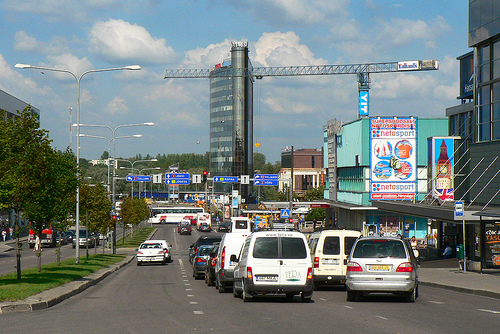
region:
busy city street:
[5, 219, 475, 332]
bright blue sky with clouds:
[0, 0, 499, 181]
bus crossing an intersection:
[138, 201, 205, 224]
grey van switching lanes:
[341, 231, 423, 304]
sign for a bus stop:
[451, 197, 470, 276]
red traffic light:
[198, 169, 208, 184]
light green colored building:
[319, 110, 452, 252]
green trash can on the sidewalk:
[453, 241, 465, 263]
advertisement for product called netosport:
[367, 111, 418, 207]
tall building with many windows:
[203, 40, 258, 207]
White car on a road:
[130, 231, 195, 274]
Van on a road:
[230, 224, 358, 303]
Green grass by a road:
[17, 254, 96, 300]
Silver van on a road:
[332, 221, 417, 299]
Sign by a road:
[361, 112, 421, 198]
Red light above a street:
[193, 164, 220, 183]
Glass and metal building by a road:
[198, 66, 270, 204]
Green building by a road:
[316, 117, 454, 224]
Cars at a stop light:
[184, 220, 309, 306]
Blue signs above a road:
[124, 145, 319, 200]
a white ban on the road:
[231, 229, 315, 299]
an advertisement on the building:
[368, 116, 417, 205]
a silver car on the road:
[346, 236, 420, 301]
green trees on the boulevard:
[2, 105, 74, 278]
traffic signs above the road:
[122, 168, 279, 189]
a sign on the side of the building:
[428, 133, 458, 204]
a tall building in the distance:
[206, 37, 254, 175]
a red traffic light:
[111, 212, 119, 254]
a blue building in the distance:
[321, 115, 452, 205]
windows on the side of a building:
[476, 43, 498, 140]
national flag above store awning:
[435, 189, 455, 205]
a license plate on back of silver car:
[365, 260, 391, 270]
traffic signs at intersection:
[165, 171, 190, 183]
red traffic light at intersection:
[200, 167, 207, 183]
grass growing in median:
[16, 282, 27, 292]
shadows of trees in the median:
[28, 270, 65, 280]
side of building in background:
[210, 116, 233, 147]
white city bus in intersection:
[150, 205, 202, 221]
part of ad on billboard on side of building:
[371, 135, 413, 185]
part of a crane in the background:
[346, 59, 382, 88]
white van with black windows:
[240, 230, 319, 298]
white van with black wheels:
[230, 227, 314, 294]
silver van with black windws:
[342, 233, 419, 303]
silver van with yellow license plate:
[345, 232, 421, 304]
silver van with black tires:
[345, 233, 419, 302]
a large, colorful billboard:
[367, 115, 416, 200]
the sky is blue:
[3, 2, 495, 147]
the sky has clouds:
[0, 5, 498, 159]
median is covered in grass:
[4, 248, 135, 320]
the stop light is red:
[199, 165, 214, 188]